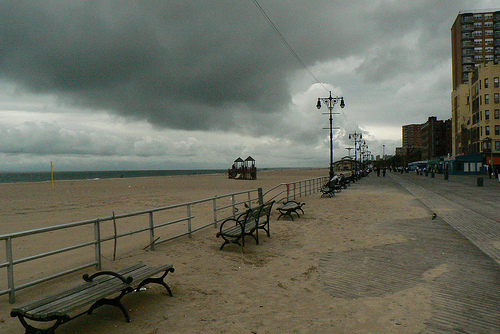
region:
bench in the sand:
[12, 251, 181, 332]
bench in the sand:
[211, 195, 283, 255]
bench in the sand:
[273, 193, 305, 222]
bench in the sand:
[316, 179, 341, 200]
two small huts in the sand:
[224, 153, 266, 185]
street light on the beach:
[310, 86, 350, 191]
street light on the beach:
[343, 126, 365, 163]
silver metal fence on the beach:
[0, 177, 269, 310]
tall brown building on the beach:
[437, 6, 498, 86]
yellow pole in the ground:
[45, 155, 57, 187]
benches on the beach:
[92, 101, 456, 318]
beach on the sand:
[167, 146, 358, 285]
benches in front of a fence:
[21, 156, 368, 321]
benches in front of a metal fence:
[111, 133, 418, 304]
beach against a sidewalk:
[197, 112, 497, 264]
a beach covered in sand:
[47, 148, 312, 332]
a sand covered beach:
[41, 148, 272, 329]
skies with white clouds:
[46, 5, 315, 193]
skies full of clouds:
[28, 9, 232, 185]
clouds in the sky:
[26, 8, 233, 183]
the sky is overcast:
[13, 27, 378, 167]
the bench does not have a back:
[8, 227, 201, 321]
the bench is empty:
[204, 177, 291, 267]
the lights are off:
[273, 78, 359, 133]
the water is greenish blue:
[0, 144, 164, 196]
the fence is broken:
[70, 205, 197, 260]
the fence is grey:
[1, 209, 196, 274]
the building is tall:
[419, 9, 495, 136]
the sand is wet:
[16, 172, 193, 283]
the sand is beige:
[49, 160, 215, 270]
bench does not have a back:
[27, 241, 193, 333]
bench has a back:
[216, 200, 280, 235]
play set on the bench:
[223, 149, 258, 184]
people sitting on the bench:
[322, 163, 351, 187]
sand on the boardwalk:
[306, 190, 437, 310]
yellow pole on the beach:
[46, 154, 61, 188]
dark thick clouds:
[45, 8, 282, 95]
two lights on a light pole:
[313, 94, 349, 125]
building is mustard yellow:
[439, 67, 498, 183]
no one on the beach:
[65, 162, 190, 199]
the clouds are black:
[112, 28, 202, 133]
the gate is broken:
[98, 219, 163, 269]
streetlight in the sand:
[293, 73, 360, 206]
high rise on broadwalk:
[446, 10, 488, 90]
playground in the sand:
[225, 159, 257, 189]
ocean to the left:
[85, 154, 190, 230]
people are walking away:
[370, 152, 411, 185]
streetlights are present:
[305, 81, 387, 178]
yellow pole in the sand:
[37, 154, 69, 212]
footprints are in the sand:
[221, 278, 298, 312]